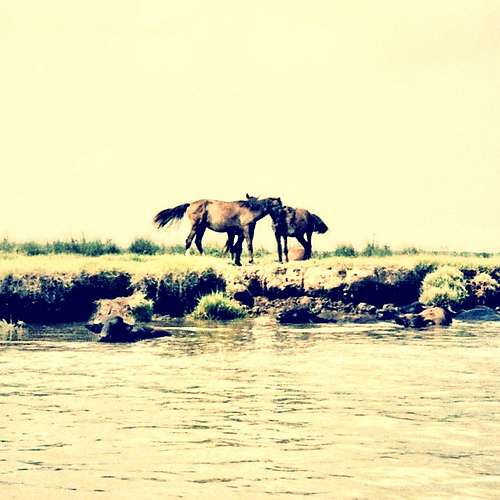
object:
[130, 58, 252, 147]
clouds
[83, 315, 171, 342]
animal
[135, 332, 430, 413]
water flowing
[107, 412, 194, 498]
water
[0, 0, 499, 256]
skies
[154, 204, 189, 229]
tail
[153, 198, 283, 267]
horse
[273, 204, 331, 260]
horse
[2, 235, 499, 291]
field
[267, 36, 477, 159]
clouds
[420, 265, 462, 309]
grass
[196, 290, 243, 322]
grass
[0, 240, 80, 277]
grass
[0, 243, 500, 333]
bank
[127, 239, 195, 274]
grass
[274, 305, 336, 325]
swimming cow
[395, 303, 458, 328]
swimming cow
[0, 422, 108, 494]
water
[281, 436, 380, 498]
water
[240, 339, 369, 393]
water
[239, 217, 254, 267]
legs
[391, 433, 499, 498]
water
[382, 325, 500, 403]
water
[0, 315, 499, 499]
river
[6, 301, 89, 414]
water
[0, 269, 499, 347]
marsh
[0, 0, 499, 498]
photo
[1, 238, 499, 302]
field